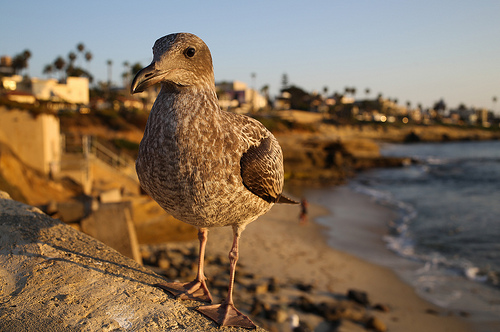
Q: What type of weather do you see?
A: It is clear.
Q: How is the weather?
A: It is clear.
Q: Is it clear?
A: Yes, it is clear.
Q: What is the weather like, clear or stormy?
A: It is clear.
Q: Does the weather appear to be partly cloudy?
A: No, it is clear.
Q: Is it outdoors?
A: Yes, it is outdoors.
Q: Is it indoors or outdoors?
A: It is outdoors.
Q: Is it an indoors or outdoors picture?
A: It is outdoors.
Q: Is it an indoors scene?
A: No, it is outdoors.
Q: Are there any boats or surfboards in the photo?
A: No, there are no boats or surfboards.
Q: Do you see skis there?
A: No, there are no skis.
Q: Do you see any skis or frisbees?
A: No, there are no skis or frisbees.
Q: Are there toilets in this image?
A: No, there are no toilets.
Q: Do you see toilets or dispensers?
A: No, there are no toilets or dispensers.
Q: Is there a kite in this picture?
A: No, there are no kites.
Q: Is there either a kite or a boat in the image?
A: No, there are no kites or boats.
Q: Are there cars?
A: No, there are no cars.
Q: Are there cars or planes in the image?
A: No, there are no cars or planes.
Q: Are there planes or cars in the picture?
A: No, there are no cars or planes.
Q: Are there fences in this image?
A: No, there are no fences.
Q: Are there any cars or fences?
A: No, there are no fences or cars.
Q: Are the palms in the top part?
A: Yes, the palms are in the top of the image.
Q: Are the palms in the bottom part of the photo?
A: No, the palms are in the top of the image.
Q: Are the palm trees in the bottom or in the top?
A: The palm trees are in the top of the image.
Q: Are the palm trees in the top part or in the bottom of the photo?
A: The palm trees are in the top of the image.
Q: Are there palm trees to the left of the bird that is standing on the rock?
A: Yes, there are palm trees to the left of the bird.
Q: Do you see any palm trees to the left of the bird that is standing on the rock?
A: Yes, there are palm trees to the left of the bird.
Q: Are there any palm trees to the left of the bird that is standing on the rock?
A: Yes, there are palm trees to the left of the bird.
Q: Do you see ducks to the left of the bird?
A: No, there are palm trees to the left of the bird.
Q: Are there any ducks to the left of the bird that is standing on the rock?
A: No, there are palm trees to the left of the bird.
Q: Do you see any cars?
A: No, there are no cars.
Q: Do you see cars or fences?
A: No, there are no cars or fences.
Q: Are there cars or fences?
A: No, there are no cars or fences.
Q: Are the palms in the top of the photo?
A: Yes, the palms are in the top of the image.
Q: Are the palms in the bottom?
A: No, the palms are in the top of the image.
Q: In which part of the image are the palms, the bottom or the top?
A: The palms are in the top of the image.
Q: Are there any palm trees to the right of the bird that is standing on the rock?
A: Yes, there are palm trees to the right of the bird.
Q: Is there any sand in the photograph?
A: Yes, there is sand.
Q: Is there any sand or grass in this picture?
A: Yes, there is sand.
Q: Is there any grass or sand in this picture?
A: Yes, there is sand.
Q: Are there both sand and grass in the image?
A: No, there is sand but no grass.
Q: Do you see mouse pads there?
A: No, there are no mouse pads.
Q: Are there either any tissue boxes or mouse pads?
A: No, there are no mouse pads or tissue boxes.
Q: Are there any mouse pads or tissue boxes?
A: No, there are no mouse pads or tissue boxes.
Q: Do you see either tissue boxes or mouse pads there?
A: No, there are no mouse pads or tissue boxes.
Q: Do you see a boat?
A: No, there are no boats.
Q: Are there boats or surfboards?
A: No, there are no boats or surfboards.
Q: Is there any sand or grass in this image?
A: Yes, there is sand.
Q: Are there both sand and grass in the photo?
A: No, there is sand but no grass.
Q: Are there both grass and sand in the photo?
A: No, there is sand but no grass.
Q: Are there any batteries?
A: No, there are no batteries.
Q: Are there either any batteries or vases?
A: No, there are no batteries or vases.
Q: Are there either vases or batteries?
A: No, there are no batteries or vases.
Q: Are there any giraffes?
A: No, there are no giraffes.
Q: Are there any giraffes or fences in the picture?
A: No, there are no giraffes or fences.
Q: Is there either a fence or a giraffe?
A: No, there are no giraffes or fences.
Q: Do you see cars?
A: No, there are no cars.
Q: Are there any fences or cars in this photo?
A: No, there are no cars or fences.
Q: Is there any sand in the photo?
A: Yes, there is sand.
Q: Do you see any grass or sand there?
A: Yes, there is sand.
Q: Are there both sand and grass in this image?
A: No, there is sand but no grass.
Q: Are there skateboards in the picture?
A: No, there are no skateboards.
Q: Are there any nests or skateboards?
A: No, there are no skateboards or nests.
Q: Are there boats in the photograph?
A: No, there are no boats.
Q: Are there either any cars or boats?
A: No, there are no boats or cars.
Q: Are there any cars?
A: No, there are no cars.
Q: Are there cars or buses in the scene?
A: No, there are no cars or buses.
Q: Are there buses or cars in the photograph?
A: No, there are no cars or buses.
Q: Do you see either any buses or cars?
A: No, there are no cars or buses.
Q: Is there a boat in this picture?
A: No, there are no boats.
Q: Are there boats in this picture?
A: No, there are no boats.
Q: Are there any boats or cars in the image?
A: No, there are no boats or cars.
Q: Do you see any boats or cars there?
A: No, there are no boats or cars.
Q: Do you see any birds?
A: Yes, there is a bird.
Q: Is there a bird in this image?
A: Yes, there is a bird.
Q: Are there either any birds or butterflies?
A: Yes, there is a bird.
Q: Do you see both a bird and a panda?
A: No, there is a bird but no pandas.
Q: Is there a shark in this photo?
A: No, there are no sharks.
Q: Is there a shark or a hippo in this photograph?
A: No, there are no sharks or hippos.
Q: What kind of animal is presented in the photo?
A: The animal is a bird.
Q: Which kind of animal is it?
A: The animal is a bird.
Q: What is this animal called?
A: This is a bird.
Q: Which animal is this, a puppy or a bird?
A: This is a bird.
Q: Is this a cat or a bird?
A: This is a bird.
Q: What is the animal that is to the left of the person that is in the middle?
A: The animal is a bird.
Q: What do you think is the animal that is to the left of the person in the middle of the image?
A: The animal is a bird.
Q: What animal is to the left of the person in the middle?
A: The animal is a bird.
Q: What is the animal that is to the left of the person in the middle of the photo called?
A: The animal is a bird.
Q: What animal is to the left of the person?
A: The animal is a bird.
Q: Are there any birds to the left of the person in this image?
A: Yes, there is a bird to the left of the person.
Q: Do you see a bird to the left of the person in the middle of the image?
A: Yes, there is a bird to the left of the person.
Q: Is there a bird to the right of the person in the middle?
A: No, the bird is to the left of the person.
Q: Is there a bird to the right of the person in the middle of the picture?
A: No, the bird is to the left of the person.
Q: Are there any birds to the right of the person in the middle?
A: No, the bird is to the left of the person.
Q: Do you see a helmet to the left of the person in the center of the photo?
A: No, there is a bird to the left of the person.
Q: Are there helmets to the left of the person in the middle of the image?
A: No, there is a bird to the left of the person.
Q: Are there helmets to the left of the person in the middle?
A: No, there is a bird to the left of the person.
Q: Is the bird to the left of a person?
A: Yes, the bird is to the left of a person.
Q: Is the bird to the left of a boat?
A: No, the bird is to the left of a person.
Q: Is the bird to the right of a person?
A: No, the bird is to the left of a person.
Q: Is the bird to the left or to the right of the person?
A: The bird is to the left of the person.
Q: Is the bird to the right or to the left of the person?
A: The bird is to the left of the person.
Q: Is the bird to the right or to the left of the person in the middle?
A: The bird is to the left of the person.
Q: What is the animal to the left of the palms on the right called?
A: The animal is a bird.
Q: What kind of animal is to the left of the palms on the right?
A: The animal is a bird.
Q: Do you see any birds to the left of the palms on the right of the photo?
A: Yes, there is a bird to the left of the palm trees.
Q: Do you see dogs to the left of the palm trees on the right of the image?
A: No, there is a bird to the left of the palm trees.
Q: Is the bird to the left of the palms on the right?
A: Yes, the bird is to the left of the palm trees.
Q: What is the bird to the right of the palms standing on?
A: The bird is standing on the rock.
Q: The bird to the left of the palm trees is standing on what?
A: The bird is standing on the rock.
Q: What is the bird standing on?
A: The bird is standing on the rock.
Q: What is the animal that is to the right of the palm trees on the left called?
A: The animal is a bird.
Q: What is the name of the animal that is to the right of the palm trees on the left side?
A: The animal is a bird.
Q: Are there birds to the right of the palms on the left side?
A: Yes, there is a bird to the right of the palms.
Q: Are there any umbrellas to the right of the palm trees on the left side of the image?
A: No, there is a bird to the right of the palms.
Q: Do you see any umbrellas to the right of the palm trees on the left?
A: No, there is a bird to the right of the palms.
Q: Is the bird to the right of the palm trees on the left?
A: Yes, the bird is to the right of the palms.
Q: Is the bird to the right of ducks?
A: No, the bird is to the right of the palms.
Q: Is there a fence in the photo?
A: No, there are no fences.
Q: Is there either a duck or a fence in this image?
A: No, there are no fences or ducks.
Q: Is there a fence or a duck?
A: No, there are no fences or ducks.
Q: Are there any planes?
A: No, there are no planes.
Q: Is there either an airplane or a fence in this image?
A: No, there are no airplanes or fences.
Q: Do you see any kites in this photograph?
A: No, there are no kites.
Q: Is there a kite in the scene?
A: No, there are no kites.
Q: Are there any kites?
A: No, there are no kites.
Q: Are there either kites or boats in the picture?
A: No, there are no kites or boats.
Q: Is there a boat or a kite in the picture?
A: No, there are no kites or boats.